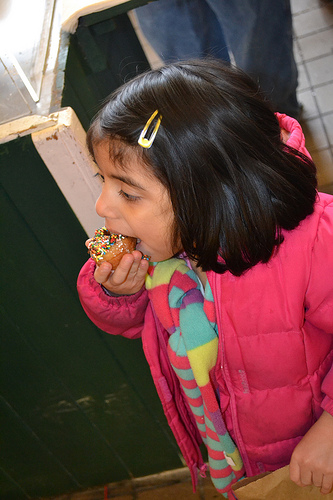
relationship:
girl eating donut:
[77, 59, 331, 468] [88, 231, 141, 267]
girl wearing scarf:
[77, 59, 331, 468] [147, 260, 244, 494]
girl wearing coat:
[77, 59, 331, 468] [75, 192, 332, 474]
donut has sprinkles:
[88, 231, 141, 267] [90, 232, 123, 259]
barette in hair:
[135, 108, 167, 146] [96, 68, 301, 256]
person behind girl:
[137, 3, 304, 109] [77, 59, 331, 468]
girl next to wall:
[77, 59, 331, 468] [0, 134, 197, 481]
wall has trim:
[0, 134, 197, 481] [30, 121, 96, 228]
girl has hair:
[77, 59, 331, 468] [96, 68, 301, 256]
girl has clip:
[77, 59, 331, 468] [135, 108, 167, 146]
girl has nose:
[77, 59, 331, 468] [96, 188, 118, 217]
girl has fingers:
[77, 59, 331, 468] [97, 257, 150, 298]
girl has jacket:
[77, 59, 331, 468] [75, 192, 332, 474]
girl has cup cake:
[77, 59, 331, 468] [88, 231, 141, 267]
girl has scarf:
[77, 59, 331, 468] [147, 260, 244, 494]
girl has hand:
[77, 59, 331, 468] [286, 431, 331, 495]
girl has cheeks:
[77, 59, 331, 468] [142, 211, 176, 251]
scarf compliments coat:
[147, 260, 244, 494] [75, 192, 332, 474]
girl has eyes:
[77, 59, 331, 468] [121, 188, 146, 200]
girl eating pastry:
[77, 59, 331, 468] [88, 234, 128, 258]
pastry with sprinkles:
[88, 234, 128, 258] [90, 232, 123, 259]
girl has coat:
[77, 59, 331, 468] [75, 192, 332, 474]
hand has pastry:
[286, 431, 331, 495] [88, 234, 128, 258]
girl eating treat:
[77, 59, 331, 468] [88, 231, 141, 267]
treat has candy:
[88, 231, 141, 267] [88, 227, 127, 249]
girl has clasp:
[77, 59, 331, 468] [135, 108, 167, 146]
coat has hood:
[75, 192, 332, 474] [249, 106, 316, 179]